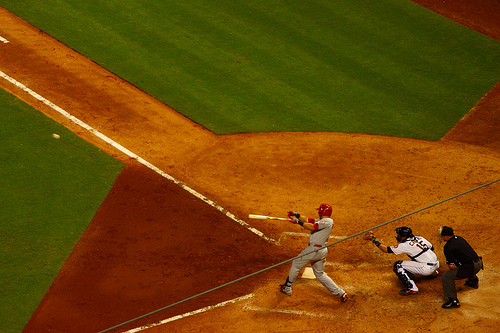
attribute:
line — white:
[203, 190, 278, 249]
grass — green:
[0, 147, 53, 259]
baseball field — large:
[0, 0, 466, 325]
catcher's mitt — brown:
[355, 225, 380, 247]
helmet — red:
[307, 197, 333, 218]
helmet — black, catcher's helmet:
[359, 216, 438, 299]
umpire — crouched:
[412, 228, 497, 303]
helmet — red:
[303, 185, 359, 221]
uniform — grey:
[294, 221, 340, 272]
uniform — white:
[400, 213, 443, 280]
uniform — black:
[436, 245, 497, 293]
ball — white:
[42, 125, 84, 136]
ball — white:
[36, 129, 82, 143]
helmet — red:
[305, 202, 336, 213]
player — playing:
[283, 185, 369, 329]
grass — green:
[0, 142, 60, 228]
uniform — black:
[423, 206, 484, 299]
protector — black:
[392, 267, 409, 283]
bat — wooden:
[232, 177, 309, 257]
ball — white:
[31, 119, 82, 161]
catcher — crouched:
[374, 185, 434, 285]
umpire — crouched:
[410, 191, 494, 311]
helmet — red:
[304, 194, 334, 224]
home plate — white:
[298, 257, 328, 292]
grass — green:
[176, 0, 459, 181]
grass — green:
[29, 143, 129, 304]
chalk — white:
[112, 280, 301, 318]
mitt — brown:
[359, 224, 369, 234]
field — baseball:
[122, 8, 417, 156]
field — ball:
[10, 10, 246, 226]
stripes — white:
[21, 80, 164, 177]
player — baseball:
[278, 199, 352, 305]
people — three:
[276, 208, 483, 311]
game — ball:
[103, 70, 486, 321]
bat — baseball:
[246, 210, 295, 227]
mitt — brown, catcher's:
[363, 229, 383, 250]